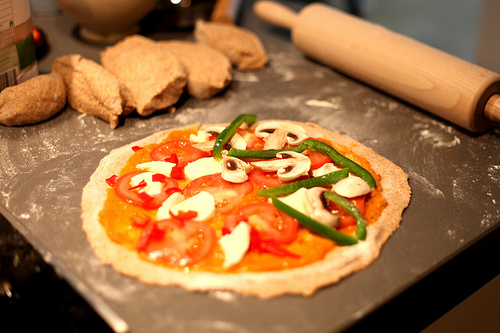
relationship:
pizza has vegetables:
[80, 111, 414, 296] [208, 113, 383, 270]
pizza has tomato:
[80, 111, 414, 296] [107, 119, 387, 281]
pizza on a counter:
[80, 111, 414, 296] [12, 12, 490, 326]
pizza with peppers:
[80, 111, 414, 296] [212, 115, 376, 253]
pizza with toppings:
[80, 111, 414, 296] [98, 119, 380, 268]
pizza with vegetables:
[80, 111, 414, 296] [208, 113, 383, 270]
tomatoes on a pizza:
[107, 119, 387, 281] [80, 111, 414, 296]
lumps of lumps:
[4, 19, 274, 131] [4, 19, 274, 131]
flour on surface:
[3, 131, 70, 232] [4, 42, 499, 328]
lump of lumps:
[0, 63, 65, 140] [4, 19, 274, 131]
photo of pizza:
[1, 4, 491, 329] [80, 111, 414, 296]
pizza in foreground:
[80, 111, 414, 296] [7, 111, 495, 329]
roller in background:
[233, 1, 499, 150] [4, 0, 499, 180]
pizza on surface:
[80, 111, 414, 296] [0, 16, 499, 325]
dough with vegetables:
[79, 115, 417, 305] [208, 113, 383, 270]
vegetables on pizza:
[208, 113, 383, 270] [80, 111, 414, 296]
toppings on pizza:
[99, 107, 393, 276] [80, 111, 414, 296]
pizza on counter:
[80, 111, 414, 296] [1, 20, 499, 326]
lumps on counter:
[4, 19, 274, 131] [1, 20, 499, 326]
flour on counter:
[14, 117, 107, 152] [12, 12, 490, 326]